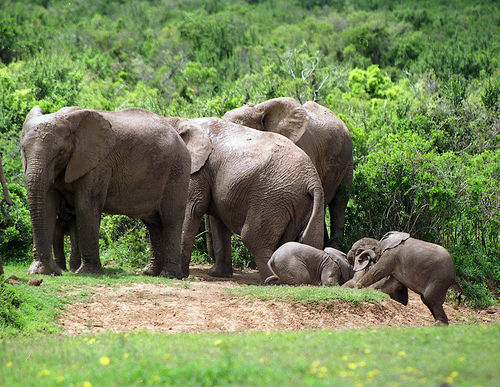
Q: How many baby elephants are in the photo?
A: 3.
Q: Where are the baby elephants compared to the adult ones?
A: Right.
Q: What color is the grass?
A: Green.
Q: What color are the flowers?
A: Yellow.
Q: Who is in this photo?
A: No person.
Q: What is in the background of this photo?
A: Trees.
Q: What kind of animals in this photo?
A: Elephant.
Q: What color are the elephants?
A: Gray.